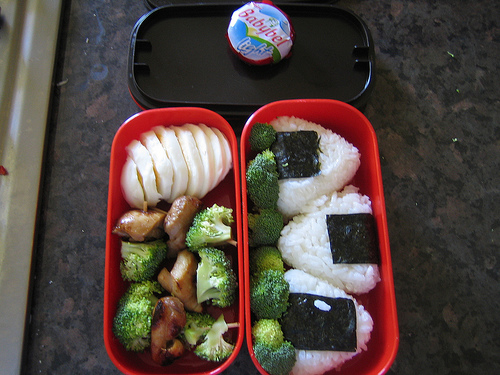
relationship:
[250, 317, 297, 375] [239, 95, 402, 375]
broccoli in container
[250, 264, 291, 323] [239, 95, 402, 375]
broccoli in container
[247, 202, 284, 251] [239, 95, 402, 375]
broccoli in container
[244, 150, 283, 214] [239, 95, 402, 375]
broccoli in container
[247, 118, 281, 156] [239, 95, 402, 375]
broccoli in container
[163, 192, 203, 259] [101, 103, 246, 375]
chicken in container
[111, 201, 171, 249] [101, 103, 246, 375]
chicken in container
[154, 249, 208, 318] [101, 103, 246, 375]
chicken in container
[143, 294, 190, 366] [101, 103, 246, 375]
chicken in container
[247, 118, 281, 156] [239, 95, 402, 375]
broccoli within container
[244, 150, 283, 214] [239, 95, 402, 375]
broccoli within container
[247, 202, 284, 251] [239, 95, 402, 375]
broccoli within container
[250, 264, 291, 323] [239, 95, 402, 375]
broccoli within container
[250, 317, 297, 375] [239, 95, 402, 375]
broccoli within container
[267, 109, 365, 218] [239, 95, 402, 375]
rice within container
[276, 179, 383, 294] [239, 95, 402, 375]
rice within container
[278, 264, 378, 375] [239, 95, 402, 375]
rice within container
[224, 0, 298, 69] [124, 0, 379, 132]
cheese on lid